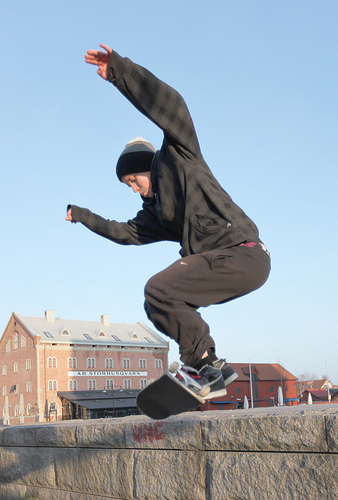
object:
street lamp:
[105, 378, 114, 390]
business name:
[68, 370, 146, 376]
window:
[67, 356, 78, 369]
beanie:
[116, 137, 157, 183]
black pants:
[142, 243, 271, 369]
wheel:
[169, 361, 179, 372]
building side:
[35, 341, 170, 423]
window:
[48, 356, 57, 368]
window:
[87, 378, 97, 391]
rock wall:
[0, 400, 337, 498]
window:
[87, 357, 97, 368]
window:
[122, 357, 131, 369]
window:
[138, 357, 148, 370]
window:
[48, 379, 58, 392]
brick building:
[2, 309, 171, 426]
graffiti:
[133, 421, 165, 443]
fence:
[0, 402, 336, 500]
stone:
[208, 449, 335, 499]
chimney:
[44, 309, 55, 324]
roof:
[17, 310, 168, 345]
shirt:
[67, 48, 259, 252]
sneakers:
[214, 358, 238, 385]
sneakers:
[177, 366, 227, 398]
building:
[198, 355, 337, 414]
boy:
[61, 40, 271, 397]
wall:
[39, 351, 166, 421]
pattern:
[1, 409, 338, 499]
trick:
[133, 356, 239, 420]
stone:
[54, 449, 133, 498]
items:
[257, 382, 269, 389]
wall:
[209, 382, 298, 409]